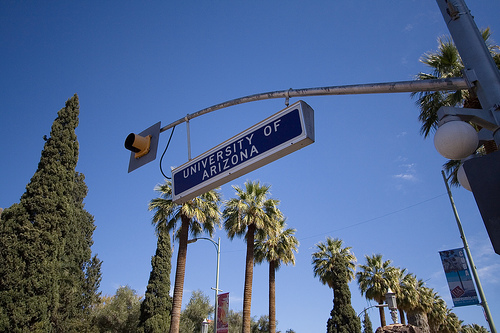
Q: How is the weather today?
A: It is cloudless.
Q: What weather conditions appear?
A: It is cloudless.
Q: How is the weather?
A: It is cloudless.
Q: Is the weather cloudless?
A: Yes, it is cloudless.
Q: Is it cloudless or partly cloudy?
A: It is cloudless.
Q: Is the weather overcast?
A: No, it is cloudless.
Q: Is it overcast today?
A: No, it is cloudless.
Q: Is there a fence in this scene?
A: No, there are no fences.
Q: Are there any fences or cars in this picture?
A: No, there are no fences or cars.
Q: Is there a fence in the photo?
A: No, there are no fences.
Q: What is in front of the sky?
A: The tree is in front of the sky.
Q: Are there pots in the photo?
A: No, there are no pots.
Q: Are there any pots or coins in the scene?
A: No, there are no pots or coins.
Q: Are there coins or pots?
A: No, there are no pots or coins.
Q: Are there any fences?
A: No, there are no fences.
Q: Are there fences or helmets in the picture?
A: No, there are no fences or helmets.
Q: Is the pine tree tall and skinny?
A: Yes, the pine tree is tall and skinny.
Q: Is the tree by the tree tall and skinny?
A: Yes, the pine tree is tall and skinny.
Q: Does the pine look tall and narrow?
A: Yes, the pine is tall and narrow.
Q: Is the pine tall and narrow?
A: Yes, the pine is tall and narrow.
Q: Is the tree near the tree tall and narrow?
A: Yes, the pine is tall and narrow.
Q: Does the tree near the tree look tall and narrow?
A: Yes, the pine is tall and narrow.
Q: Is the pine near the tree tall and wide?
A: No, the pine tree is tall but narrow.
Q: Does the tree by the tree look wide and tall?
A: No, the pine tree is tall but narrow.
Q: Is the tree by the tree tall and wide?
A: No, the pine tree is tall but narrow.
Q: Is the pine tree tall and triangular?
A: Yes, the pine tree is tall and triangular.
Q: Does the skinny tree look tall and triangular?
A: Yes, the pine tree is tall and triangular.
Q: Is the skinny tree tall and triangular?
A: Yes, the pine tree is tall and triangular.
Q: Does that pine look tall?
A: Yes, the pine is tall.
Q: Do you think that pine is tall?
A: Yes, the pine is tall.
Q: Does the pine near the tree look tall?
A: Yes, the pine is tall.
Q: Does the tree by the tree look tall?
A: Yes, the pine is tall.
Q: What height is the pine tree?
A: The pine tree is tall.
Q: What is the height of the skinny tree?
A: The pine tree is tall.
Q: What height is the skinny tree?
A: The pine tree is tall.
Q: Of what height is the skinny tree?
A: The pine tree is tall.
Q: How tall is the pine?
A: The pine is tall.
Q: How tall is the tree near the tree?
A: The pine is tall.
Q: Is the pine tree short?
A: No, the pine tree is tall.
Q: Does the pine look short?
A: No, the pine is tall.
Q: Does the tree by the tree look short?
A: No, the pine is tall.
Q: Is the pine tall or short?
A: The pine is tall.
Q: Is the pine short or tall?
A: The pine is tall.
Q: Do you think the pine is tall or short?
A: The pine is tall.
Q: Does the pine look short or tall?
A: The pine is tall.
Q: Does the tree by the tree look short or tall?
A: The pine is tall.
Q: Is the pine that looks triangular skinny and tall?
A: Yes, the pine is skinny and tall.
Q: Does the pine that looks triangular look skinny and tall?
A: Yes, the pine is skinny and tall.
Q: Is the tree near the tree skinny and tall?
A: Yes, the pine is skinny and tall.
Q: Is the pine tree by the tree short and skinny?
A: No, the pine tree is skinny but tall.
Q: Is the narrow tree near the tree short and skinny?
A: No, the pine tree is skinny but tall.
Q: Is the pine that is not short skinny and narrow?
A: Yes, the pine is skinny and narrow.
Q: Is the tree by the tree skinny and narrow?
A: Yes, the pine is skinny and narrow.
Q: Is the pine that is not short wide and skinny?
A: No, the pine is skinny but narrow.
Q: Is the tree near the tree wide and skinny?
A: No, the pine is skinny but narrow.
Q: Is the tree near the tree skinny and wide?
A: No, the pine is skinny but narrow.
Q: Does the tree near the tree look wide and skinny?
A: No, the pine is skinny but narrow.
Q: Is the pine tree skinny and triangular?
A: Yes, the pine tree is skinny and triangular.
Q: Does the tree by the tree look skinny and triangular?
A: Yes, the pine tree is skinny and triangular.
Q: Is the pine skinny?
A: Yes, the pine is skinny.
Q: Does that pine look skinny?
A: Yes, the pine is skinny.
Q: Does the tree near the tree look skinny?
A: Yes, the pine is skinny.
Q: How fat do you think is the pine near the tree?
A: The pine tree is skinny.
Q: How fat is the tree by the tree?
A: The pine tree is skinny.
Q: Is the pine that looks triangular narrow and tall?
A: Yes, the pine tree is narrow and tall.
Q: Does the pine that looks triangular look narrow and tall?
A: Yes, the pine tree is narrow and tall.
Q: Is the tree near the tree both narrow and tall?
A: Yes, the pine tree is narrow and tall.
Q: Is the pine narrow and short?
A: No, the pine is narrow but tall.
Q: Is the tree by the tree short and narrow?
A: No, the pine is narrow but tall.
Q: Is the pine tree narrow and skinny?
A: Yes, the pine tree is narrow and skinny.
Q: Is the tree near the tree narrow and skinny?
A: Yes, the pine tree is narrow and skinny.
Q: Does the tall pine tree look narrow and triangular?
A: Yes, the pine tree is narrow and triangular.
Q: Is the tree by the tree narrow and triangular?
A: Yes, the pine tree is narrow and triangular.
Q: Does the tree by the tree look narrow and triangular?
A: Yes, the pine tree is narrow and triangular.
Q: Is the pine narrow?
A: Yes, the pine is narrow.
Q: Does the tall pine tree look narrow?
A: Yes, the pine is narrow.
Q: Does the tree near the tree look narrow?
A: Yes, the pine is narrow.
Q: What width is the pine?
A: The pine is narrow.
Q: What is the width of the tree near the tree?
A: The pine is narrow.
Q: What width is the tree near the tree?
A: The pine is narrow.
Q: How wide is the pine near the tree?
A: The pine tree is narrow.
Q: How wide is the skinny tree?
A: The pine tree is narrow.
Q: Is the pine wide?
A: No, the pine is narrow.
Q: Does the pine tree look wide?
A: No, the pine tree is narrow.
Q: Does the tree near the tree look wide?
A: No, the pine tree is narrow.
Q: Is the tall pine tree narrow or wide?
A: The pine tree is narrow.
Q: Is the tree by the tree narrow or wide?
A: The pine tree is narrow.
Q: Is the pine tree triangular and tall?
A: Yes, the pine tree is triangular and tall.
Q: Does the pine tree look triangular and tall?
A: Yes, the pine tree is triangular and tall.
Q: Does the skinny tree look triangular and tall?
A: Yes, the pine tree is triangular and tall.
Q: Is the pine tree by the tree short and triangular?
A: No, the pine tree is triangular but tall.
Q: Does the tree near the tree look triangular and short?
A: No, the pine tree is triangular but tall.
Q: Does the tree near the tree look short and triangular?
A: No, the pine tree is triangular but tall.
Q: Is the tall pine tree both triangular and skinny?
A: Yes, the pine tree is triangular and skinny.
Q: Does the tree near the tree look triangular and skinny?
A: Yes, the pine tree is triangular and skinny.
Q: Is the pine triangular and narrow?
A: Yes, the pine is triangular and narrow.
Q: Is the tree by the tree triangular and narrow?
A: Yes, the pine is triangular and narrow.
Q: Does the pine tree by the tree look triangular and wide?
A: No, the pine is triangular but narrow.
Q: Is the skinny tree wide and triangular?
A: No, the pine is triangular but narrow.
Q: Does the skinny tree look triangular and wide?
A: No, the pine is triangular but narrow.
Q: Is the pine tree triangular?
A: Yes, the pine tree is triangular.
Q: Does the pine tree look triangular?
A: Yes, the pine tree is triangular.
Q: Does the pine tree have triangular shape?
A: Yes, the pine tree is triangular.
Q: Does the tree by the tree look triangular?
A: Yes, the pine tree is triangular.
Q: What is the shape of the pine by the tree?
A: The pine is triangular.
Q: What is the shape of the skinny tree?
A: The pine is triangular.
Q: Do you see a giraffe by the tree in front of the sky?
A: No, there is a pine tree by the tree.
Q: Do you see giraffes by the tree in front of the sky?
A: No, there is a pine tree by the tree.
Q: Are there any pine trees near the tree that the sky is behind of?
A: Yes, there is a pine tree near the tree.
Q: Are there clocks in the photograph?
A: No, there are no clocks.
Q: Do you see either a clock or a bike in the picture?
A: No, there are no clocks or bikes.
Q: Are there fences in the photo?
A: No, there are no fences.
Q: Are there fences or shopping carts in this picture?
A: No, there are no fences or shopping carts.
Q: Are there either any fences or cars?
A: No, there are no cars or fences.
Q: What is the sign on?
A: The sign is on the pole.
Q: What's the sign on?
A: The sign is on the pole.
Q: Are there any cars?
A: No, there are no cars.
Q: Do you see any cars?
A: No, there are no cars.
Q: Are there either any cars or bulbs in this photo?
A: No, there are no cars or bulbs.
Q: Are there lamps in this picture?
A: Yes, there is a lamp.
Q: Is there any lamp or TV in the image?
A: Yes, there is a lamp.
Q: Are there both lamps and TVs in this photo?
A: No, there is a lamp but no televisions.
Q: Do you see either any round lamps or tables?
A: Yes, there is a round lamp.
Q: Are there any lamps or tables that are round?
A: Yes, the lamp is round.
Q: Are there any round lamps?
A: Yes, there is a round lamp.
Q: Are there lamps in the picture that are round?
A: Yes, there is a lamp that is round.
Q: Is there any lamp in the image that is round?
A: Yes, there is a lamp that is round.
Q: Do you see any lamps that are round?
A: Yes, there is a lamp that is round.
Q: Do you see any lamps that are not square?
A: Yes, there is a round lamp.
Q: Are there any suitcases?
A: No, there are no suitcases.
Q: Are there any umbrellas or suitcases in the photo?
A: No, there are no suitcases or umbrellas.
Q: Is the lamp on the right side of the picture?
A: Yes, the lamp is on the right of the image.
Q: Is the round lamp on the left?
A: No, the lamp is on the right of the image.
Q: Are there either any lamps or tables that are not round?
A: No, there is a lamp but it is round.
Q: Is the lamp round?
A: Yes, the lamp is round.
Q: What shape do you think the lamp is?
A: The lamp is round.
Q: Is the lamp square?
A: No, the lamp is round.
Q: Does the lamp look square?
A: No, the lamp is round.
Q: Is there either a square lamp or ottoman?
A: No, there is a lamp but it is round.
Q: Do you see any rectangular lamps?
A: No, there is a lamp but it is round.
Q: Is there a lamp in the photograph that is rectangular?
A: No, there is a lamp but it is round.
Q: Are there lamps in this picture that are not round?
A: No, there is a lamp but it is round.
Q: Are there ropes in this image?
A: No, there are no ropes.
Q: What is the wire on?
A: The wire is on the pole.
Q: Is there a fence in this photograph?
A: No, there are no fences.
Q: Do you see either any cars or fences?
A: No, there are no fences or cars.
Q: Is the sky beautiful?
A: Yes, the sky is beautiful.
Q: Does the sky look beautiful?
A: Yes, the sky is beautiful.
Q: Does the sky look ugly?
A: No, the sky is beautiful.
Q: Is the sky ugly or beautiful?
A: The sky is beautiful.